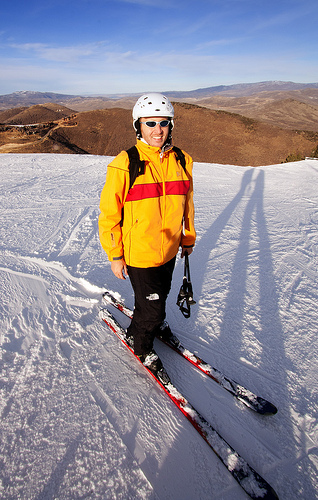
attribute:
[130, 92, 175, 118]
helmet — white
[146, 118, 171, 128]
sunglasses — blue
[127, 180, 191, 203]
stripe — red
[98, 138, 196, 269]
jacket — yellow, colored, thick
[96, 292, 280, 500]
skis — snowy, colored, red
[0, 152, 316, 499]
snow — here, white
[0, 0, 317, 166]
mountains — brown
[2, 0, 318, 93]
sky — bright, colored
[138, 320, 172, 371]
boots — black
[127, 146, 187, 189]
straps — black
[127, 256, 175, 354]
pants — black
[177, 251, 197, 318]
poles — black